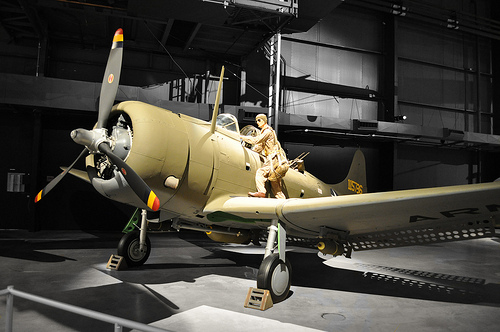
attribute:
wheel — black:
[107, 220, 160, 267]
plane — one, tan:
[22, 38, 485, 300]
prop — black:
[30, 22, 158, 223]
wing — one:
[208, 169, 498, 250]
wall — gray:
[232, 39, 466, 152]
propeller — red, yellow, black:
[16, 30, 157, 229]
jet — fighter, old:
[50, 35, 480, 308]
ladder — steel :
[256, 24, 296, 141]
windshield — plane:
[208, 111, 245, 138]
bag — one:
[262, 144, 292, 188]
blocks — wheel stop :
[241, 284, 266, 305]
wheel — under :
[255, 255, 295, 295]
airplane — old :
[14, 21, 484, 322]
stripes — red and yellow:
[146, 188, 162, 210]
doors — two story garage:
[279, 1, 474, 219]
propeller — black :
[14, 22, 170, 220]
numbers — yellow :
[345, 180, 368, 192]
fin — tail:
[345, 145, 371, 191]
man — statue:
[246, 111, 299, 194]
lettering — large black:
[405, 207, 484, 234]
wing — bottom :
[216, 169, 484, 267]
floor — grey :
[301, 296, 381, 329]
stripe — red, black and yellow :
[146, 190, 164, 207]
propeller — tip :
[112, 148, 172, 228]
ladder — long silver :
[266, 33, 282, 138]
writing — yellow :
[103, 70, 113, 81]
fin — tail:
[108, 144, 168, 210]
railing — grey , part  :
[136, 63, 301, 123]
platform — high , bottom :
[24, 245, 311, 330]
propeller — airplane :
[21, 23, 183, 223]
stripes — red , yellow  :
[143, 172, 166, 213]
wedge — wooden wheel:
[243, 279, 273, 312]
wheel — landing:
[115, 226, 143, 261]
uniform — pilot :
[242, 124, 287, 193]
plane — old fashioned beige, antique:
[17, 23, 498, 304]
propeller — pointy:
[26, 21, 167, 224]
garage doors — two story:
[275, 10, 469, 223]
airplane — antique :
[36, 23, 484, 293]